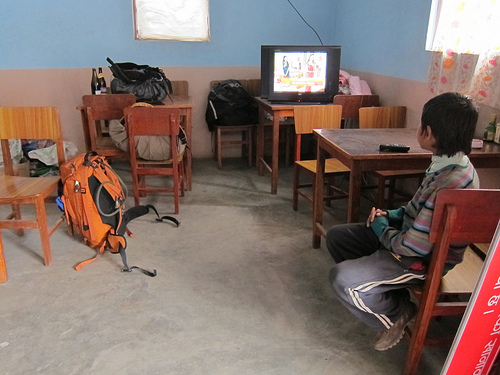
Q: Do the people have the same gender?
A: No, they are both male and female.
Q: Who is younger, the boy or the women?
A: The boy is younger than the women.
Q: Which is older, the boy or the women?
A: The women is older than the boy.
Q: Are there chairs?
A: Yes, there is a chair.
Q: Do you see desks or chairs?
A: Yes, there is a chair.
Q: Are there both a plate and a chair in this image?
A: No, there is a chair but no plates.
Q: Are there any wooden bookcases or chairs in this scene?
A: Yes, there is a wood chair.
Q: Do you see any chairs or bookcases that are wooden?
A: Yes, the chair is wooden.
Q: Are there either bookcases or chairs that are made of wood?
A: Yes, the chair is made of wood.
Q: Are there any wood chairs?
A: Yes, there is a wood chair.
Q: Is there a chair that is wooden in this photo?
A: Yes, there is a wood chair.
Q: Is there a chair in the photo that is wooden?
A: Yes, there is a chair that is wooden.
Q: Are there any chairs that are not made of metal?
A: Yes, there is a chair that is made of wood.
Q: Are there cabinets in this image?
A: No, there are no cabinets.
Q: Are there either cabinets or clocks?
A: No, there are no cabinets or clocks.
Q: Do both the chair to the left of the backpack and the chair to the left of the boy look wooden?
A: Yes, both the chair and the chair are wooden.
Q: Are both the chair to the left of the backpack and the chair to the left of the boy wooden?
A: Yes, both the chair and the chair are wooden.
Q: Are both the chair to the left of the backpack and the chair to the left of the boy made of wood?
A: Yes, both the chair and the chair are made of wood.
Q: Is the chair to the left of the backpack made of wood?
A: Yes, the chair is made of wood.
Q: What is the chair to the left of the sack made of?
A: The chair is made of wood.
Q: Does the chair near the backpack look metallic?
A: No, the chair is wooden.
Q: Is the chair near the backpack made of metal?
A: No, the chair is made of wood.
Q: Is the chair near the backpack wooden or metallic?
A: The chair is wooden.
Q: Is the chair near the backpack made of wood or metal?
A: The chair is made of wood.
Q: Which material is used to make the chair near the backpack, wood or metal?
A: The chair is made of wood.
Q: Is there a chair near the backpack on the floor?
A: Yes, there is a chair near the backpack.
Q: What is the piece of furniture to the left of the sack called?
A: The piece of furniture is a chair.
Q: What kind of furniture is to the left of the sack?
A: The piece of furniture is a chair.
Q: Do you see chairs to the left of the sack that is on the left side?
A: Yes, there is a chair to the left of the sack.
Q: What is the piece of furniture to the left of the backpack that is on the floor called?
A: The piece of furniture is a chair.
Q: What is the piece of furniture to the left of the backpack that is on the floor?
A: The piece of furniture is a chair.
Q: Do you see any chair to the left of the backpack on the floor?
A: Yes, there is a chair to the left of the backpack.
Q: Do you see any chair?
A: Yes, there is a chair.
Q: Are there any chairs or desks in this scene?
A: Yes, there is a chair.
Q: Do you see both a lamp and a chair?
A: No, there is a chair but no lamps.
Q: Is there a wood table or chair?
A: Yes, there is a wood chair.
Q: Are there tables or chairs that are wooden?
A: Yes, the chair is wooden.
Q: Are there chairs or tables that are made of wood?
A: Yes, the chair is made of wood.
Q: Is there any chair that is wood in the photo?
A: Yes, there is a wood chair.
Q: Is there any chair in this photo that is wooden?
A: Yes, there is a chair that is wooden.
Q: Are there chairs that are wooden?
A: Yes, there is a chair that is wooden.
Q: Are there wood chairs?
A: Yes, there is a chair that is made of wood.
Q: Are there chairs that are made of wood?
A: Yes, there is a chair that is made of wood.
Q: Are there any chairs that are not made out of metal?
A: Yes, there is a chair that is made of wood.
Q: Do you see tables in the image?
A: Yes, there is a table.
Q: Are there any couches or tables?
A: Yes, there is a table.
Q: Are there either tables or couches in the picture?
A: Yes, there is a table.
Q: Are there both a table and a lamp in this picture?
A: No, there is a table but no lamps.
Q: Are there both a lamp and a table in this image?
A: No, there is a table but no lamps.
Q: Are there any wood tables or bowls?
A: Yes, there is a wood table.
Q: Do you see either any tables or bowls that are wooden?
A: Yes, the table is wooden.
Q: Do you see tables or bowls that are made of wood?
A: Yes, the table is made of wood.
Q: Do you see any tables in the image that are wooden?
A: Yes, there is a table that is wooden.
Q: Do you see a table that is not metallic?
A: Yes, there is a wooden table.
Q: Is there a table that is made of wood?
A: Yes, there is a table that is made of wood.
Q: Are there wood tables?
A: Yes, there is a table that is made of wood.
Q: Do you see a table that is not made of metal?
A: Yes, there is a table that is made of wood.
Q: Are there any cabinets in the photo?
A: No, there are no cabinets.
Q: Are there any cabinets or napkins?
A: No, there are no cabinets or napkins.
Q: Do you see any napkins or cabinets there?
A: No, there are no cabinets or napkins.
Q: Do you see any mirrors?
A: No, there are no mirrors.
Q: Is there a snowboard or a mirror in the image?
A: No, there are no mirrors or snowboards.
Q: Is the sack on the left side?
A: Yes, the sack is on the left of the image.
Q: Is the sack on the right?
A: No, the sack is on the left of the image.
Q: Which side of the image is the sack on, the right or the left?
A: The sack is on the left of the image.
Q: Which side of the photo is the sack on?
A: The sack is on the left of the image.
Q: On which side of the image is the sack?
A: The sack is on the left of the image.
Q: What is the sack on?
A: The sack is on the chair.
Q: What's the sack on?
A: The sack is on the chair.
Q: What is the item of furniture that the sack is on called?
A: The piece of furniture is a chair.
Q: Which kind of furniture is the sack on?
A: The sack is on the chair.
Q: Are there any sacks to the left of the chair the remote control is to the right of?
A: Yes, there is a sack to the left of the chair.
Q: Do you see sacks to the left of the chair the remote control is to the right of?
A: Yes, there is a sack to the left of the chair.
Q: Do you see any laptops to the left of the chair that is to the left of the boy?
A: No, there is a sack to the left of the chair.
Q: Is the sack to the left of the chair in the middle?
A: Yes, the sack is to the left of the chair.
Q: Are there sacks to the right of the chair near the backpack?
A: Yes, there is a sack to the right of the chair.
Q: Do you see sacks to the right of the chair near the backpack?
A: Yes, there is a sack to the right of the chair.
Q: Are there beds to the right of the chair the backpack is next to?
A: No, there is a sack to the right of the chair.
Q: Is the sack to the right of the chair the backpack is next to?
A: Yes, the sack is to the right of the chair.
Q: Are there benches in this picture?
A: No, there are no benches.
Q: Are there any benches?
A: No, there are no benches.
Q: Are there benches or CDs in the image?
A: No, there are no benches or cds.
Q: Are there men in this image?
A: No, there are no men.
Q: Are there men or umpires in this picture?
A: No, there are no men or umpires.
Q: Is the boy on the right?
A: Yes, the boy is on the right of the image.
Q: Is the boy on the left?
A: No, the boy is on the right of the image.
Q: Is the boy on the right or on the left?
A: The boy is on the right of the image.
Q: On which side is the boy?
A: The boy is on the right of the image.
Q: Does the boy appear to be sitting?
A: Yes, the boy is sitting.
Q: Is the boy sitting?
A: Yes, the boy is sitting.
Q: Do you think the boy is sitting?
A: Yes, the boy is sitting.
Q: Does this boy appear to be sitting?
A: Yes, the boy is sitting.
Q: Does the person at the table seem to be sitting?
A: Yes, the boy is sitting.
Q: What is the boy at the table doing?
A: The boy is sitting.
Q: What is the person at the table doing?
A: The boy is sitting.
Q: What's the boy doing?
A: The boy is sitting.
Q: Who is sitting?
A: The boy is sitting.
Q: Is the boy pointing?
A: No, the boy is sitting.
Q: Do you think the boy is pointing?
A: No, the boy is sitting.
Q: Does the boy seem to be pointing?
A: No, the boy is sitting.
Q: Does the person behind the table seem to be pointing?
A: No, the boy is sitting.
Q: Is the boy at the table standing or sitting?
A: The boy is sitting.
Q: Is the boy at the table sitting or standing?
A: The boy is sitting.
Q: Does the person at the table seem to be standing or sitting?
A: The boy is sitting.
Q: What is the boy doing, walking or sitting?
A: The boy is sitting.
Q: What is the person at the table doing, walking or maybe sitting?
A: The boy is sitting.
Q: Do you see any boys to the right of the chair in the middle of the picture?
A: Yes, there is a boy to the right of the chair.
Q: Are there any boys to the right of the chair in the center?
A: Yes, there is a boy to the right of the chair.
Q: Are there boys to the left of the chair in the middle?
A: No, the boy is to the right of the chair.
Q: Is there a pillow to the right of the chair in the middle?
A: No, there is a boy to the right of the chair.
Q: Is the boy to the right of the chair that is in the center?
A: Yes, the boy is to the right of the chair.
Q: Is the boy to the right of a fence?
A: No, the boy is to the right of the chair.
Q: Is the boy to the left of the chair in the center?
A: No, the boy is to the right of the chair.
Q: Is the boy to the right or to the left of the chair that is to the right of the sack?
A: The boy is to the right of the chair.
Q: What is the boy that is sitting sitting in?
A: The boy is sitting in the chair.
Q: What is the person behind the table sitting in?
A: The boy is sitting in the chair.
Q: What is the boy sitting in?
A: The boy is sitting in the chair.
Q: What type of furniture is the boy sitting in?
A: The boy is sitting in the chair.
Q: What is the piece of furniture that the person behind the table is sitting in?
A: The piece of furniture is a chair.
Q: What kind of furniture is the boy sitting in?
A: The boy is sitting in the chair.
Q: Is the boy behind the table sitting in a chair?
A: Yes, the boy is sitting in a chair.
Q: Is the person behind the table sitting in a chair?
A: Yes, the boy is sitting in a chair.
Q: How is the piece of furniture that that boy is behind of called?
A: The piece of furniture is a table.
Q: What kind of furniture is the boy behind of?
A: The boy is behind the table.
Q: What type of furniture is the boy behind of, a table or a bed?
A: The boy is behind a table.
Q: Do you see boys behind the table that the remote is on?
A: Yes, there is a boy behind the table.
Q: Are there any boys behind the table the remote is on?
A: Yes, there is a boy behind the table.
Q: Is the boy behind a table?
A: Yes, the boy is behind a table.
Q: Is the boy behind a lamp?
A: No, the boy is behind a table.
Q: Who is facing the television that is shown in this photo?
A: The boy is facing the television.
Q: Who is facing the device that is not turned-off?
A: The boy is facing the television.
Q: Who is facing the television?
A: The boy is facing the television.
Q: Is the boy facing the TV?
A: Yes, the boy is facing the TV.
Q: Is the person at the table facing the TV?
A: Yes, the boy is facing the TV.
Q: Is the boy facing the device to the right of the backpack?
A: Yes, the boy is facing the TV.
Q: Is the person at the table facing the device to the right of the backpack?
A: Yes, the boy is facing the TV.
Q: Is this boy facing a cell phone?
A: No, the boy is facing the TV.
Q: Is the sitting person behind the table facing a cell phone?
A: No, the boy is facing the TV.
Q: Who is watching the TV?
A: The boy is watching the TV.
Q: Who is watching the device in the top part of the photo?
A: The boy is watching the TV.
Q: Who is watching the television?
A: The boy is watching the TV.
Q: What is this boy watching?
A: The boy is watching the television.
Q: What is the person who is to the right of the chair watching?
A: The boy is watching the television.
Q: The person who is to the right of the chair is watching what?
A: The boy is watching the television.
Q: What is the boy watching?
A: The boy is watching the television.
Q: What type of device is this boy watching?
A: The boy is watching the TV.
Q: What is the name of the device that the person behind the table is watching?
A: The device is a television.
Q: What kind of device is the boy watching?
A: The boy is watching the TV.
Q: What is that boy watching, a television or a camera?
A: The boy is watching a television.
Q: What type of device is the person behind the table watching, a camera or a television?
A: The boy is watching a television.